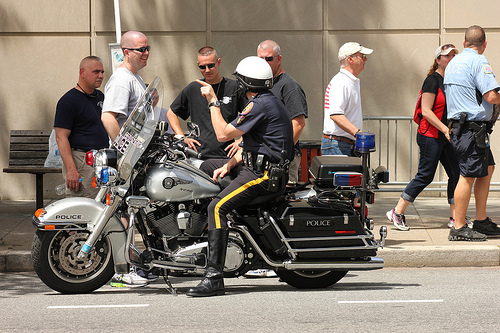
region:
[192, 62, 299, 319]
Man on a motorcycle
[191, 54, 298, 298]
Policeman on a motorcycle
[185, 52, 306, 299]
Police officer on a motorcycle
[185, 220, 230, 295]
Man is wearing boots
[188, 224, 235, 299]
Policeman is wearing boots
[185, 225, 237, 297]
Police officer is wearing boots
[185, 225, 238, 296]
Man is wearing black boots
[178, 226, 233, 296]
Police officer is wearing black boots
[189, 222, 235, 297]
Policeman is wearing black boots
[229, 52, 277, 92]
Man is wearing a helmet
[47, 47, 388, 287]
Police officer on a motorcycle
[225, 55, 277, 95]
Helmet on the policeman's head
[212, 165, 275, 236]
Yellow stripe on the pants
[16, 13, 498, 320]
Photo taken during the day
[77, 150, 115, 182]
Red and blue lights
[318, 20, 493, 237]
People walking on the sidewalk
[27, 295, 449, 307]
White lines on the road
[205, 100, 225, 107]
Watch on the left wrist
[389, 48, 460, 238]
One woman in the photo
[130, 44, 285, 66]
Sunglasses on the men's faces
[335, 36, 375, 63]
a white baseball cap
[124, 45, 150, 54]
dark black sunglasses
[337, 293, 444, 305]
a long white line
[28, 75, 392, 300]
a police motorcycle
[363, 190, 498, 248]
part of a sidewalk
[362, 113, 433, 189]
part of a gray gate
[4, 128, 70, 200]
part of a wooden bench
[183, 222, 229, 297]
a man's black boot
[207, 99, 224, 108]
a man's black watch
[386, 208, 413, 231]
a woman's tennis shoe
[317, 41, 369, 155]
man walking on street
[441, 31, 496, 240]
man walking on street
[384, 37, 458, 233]
woman walking on street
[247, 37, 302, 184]
man standing on sidewalk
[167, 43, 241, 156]
man standing on sidewalk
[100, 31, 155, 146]
man standing on sidewalk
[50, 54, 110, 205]
man standing on sidewalk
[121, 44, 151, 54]
dark colored sun glasses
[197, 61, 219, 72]
dark colored sun glasses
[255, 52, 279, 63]
dark colored sun glasses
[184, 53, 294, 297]
A police officer on a motorcycle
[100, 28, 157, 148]
a man in a grey shirt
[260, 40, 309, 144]
a man in a black shirt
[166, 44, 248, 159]
a man in a black shirt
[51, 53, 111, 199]
a man in a black shirt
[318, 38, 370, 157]
a man in a white shirt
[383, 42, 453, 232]
a woman in a red and black shirt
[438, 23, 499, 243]
a police officer on the sidewalk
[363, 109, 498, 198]
a metal barrier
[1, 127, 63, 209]
a wooden bench on the sidewalk